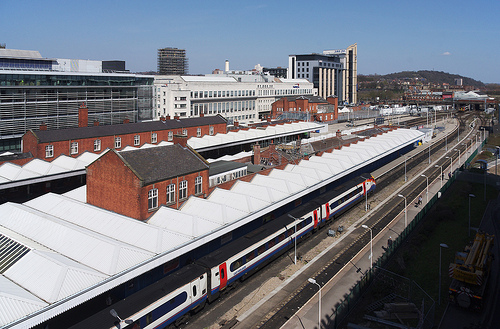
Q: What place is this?
A: It is a station.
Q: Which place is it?
A: It is a station.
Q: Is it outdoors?
A: Yes, it is outdoors.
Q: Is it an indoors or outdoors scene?
A: It is outdoors.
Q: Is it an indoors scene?
A: No, it is outdoors.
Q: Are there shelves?
A: No, there are no shelves.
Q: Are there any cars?
A: No, there are no cars.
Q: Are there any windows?
A: Yes, there is a window.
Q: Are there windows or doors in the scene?
A: Yes, there is a window.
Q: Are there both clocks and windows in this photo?
A: No, there is a window but no clocks.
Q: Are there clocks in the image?
A: No, there are no clocks.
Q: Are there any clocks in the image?
A: No, there are no clocks.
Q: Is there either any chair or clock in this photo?
A: No, there are no clocks or chairs.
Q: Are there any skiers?
A: No, there are no skiers.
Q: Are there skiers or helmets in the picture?
A: No, there are no skiers or helmets.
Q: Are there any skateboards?
A: No, there are no skateboards.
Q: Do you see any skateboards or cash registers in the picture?
A: No, there are no skateboards or cash registers.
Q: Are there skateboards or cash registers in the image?
A: No, there are no skateboards or cash registers.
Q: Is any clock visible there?
A: No, there are no clocks.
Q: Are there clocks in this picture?
A: No, there are no clocks.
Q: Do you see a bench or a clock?
A: No, there are no clocks or benches.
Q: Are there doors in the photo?
A: Yes, there is a door.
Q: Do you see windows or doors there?
A: Yes, there is a door.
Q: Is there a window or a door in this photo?
A: Yes, there is a door.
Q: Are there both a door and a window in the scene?
A: Yes, there are both a door and a window.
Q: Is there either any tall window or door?
A: Yes, there is a tall door.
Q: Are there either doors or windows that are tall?
A: Yes, the door is tall.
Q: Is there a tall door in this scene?
A: Yes, there is a tall door.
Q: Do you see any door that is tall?
A: Yes, there is a door that is tall.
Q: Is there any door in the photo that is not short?
A: Yes, there is a tall door.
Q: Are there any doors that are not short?
A: Yes, there is a tall door.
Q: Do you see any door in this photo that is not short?
A: Yes, there is a tall door.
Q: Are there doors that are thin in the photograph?
A: Yes, there is a thin door.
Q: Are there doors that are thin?
A: Yes, there is a door that is thin.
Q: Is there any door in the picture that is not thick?
A: Yes, there is a thin door.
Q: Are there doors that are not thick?
A: Yes, there is a thin door.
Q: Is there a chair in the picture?
A: No, there are no chairs.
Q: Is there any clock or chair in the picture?
A: No, there are no chairs or clocks.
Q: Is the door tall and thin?
A: Yes, the door is tall and thin.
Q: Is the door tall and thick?
A: No, the door is tall but thin.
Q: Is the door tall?
A: Yes, the door is tall.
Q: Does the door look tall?
A: Yes, the door is tall.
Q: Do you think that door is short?
A: No, the door is tall.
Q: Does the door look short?
A: No, the door is tall.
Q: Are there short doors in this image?
A: No, there is a door but it is tall.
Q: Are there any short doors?
A: No, there is a door but it is tall.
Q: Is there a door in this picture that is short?
A: No, there is a door but it is tall.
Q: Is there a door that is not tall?
A: No, there is a door but it is tall.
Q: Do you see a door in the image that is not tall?
A: No, there is a door but it is tall.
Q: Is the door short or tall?
A: The door is tall.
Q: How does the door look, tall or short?
A: The door is tall.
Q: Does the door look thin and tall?
A: Yes, the door is thin and tall.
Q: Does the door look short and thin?
A: No, the door is thin but tall.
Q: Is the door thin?
A: Yes, the door is thin.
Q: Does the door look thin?
A: Yes, the door is thin.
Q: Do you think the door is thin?
A: Yes, the door is thin.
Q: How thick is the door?
A: The door is thin.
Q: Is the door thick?
A: No, the door is thin.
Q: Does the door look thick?
A: No, the door is thin.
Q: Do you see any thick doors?
A: No, there is a door but it is thin.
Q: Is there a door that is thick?
A: No, there is a door but it is thin.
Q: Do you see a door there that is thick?
A: No, there is a door but it is thin.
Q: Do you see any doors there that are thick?
A: No, there is a door but it is thin.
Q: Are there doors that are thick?
A: No, there is a door but it is thin.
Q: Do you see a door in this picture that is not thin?
A: No, there is a door but it is thin.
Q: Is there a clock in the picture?
A: No, there are no clocks.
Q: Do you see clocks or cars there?
A: No, there are no clocks or cars.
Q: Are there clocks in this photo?
A: No, there are no clocks.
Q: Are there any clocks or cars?
A: No, there are no clocks or cars.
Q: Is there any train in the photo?
A: Yes, there is a train.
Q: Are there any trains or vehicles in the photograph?
A: Yes, there is a train.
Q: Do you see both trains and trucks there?
A: No, there is a train but no trucks.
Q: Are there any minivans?
A: No, there are no minivans.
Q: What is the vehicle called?
A: The vehicle is a train.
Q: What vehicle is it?
A: The vehicle is a train.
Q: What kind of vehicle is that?
A: This is a train.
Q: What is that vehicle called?
A: This is a train.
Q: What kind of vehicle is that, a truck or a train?
A: This is a train.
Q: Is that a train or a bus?
A: That is a train.